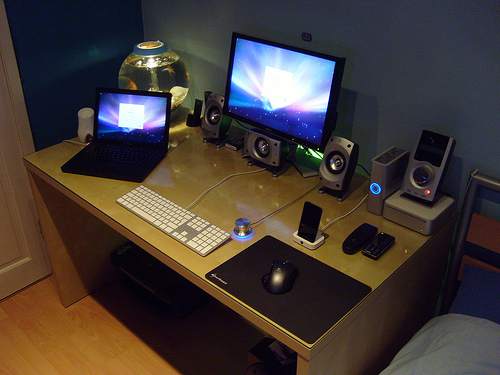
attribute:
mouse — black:
[263, 257, 298, 295]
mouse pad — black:
[203, 234, 371, 346]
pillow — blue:
[444, 263, 499, 326]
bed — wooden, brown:
[375, 167, 499, 374]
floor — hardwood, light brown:
[0, 272, 265, 372]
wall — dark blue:
[3, 0, 145, 151]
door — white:
[1, 57, 49, 308]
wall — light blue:
[142, 1, 499, 217]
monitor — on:
[219, 29, 345, 151]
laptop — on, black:
[61, 87, 171, 184]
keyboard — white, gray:
[116, 184, 231, 256]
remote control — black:
[340, 219, 378, 254]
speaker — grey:
[198, 89, 231, 148]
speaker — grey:
[314, 135, 359, 201]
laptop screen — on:
[96, 90, 168, 144]